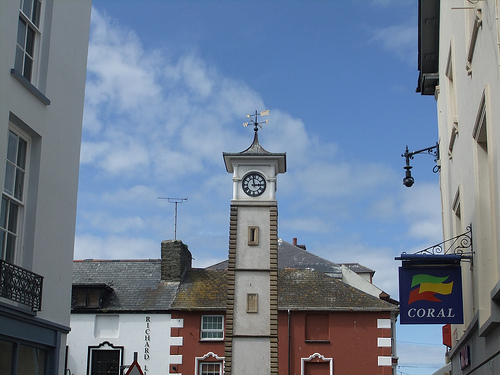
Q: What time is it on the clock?
A: 12:15.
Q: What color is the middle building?
A: Pale Brown.